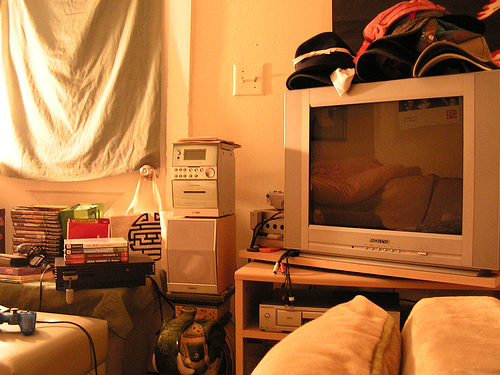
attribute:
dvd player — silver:
[260, 288, 329, 336]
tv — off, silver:
[283, 68, 499, 278]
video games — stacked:
[12, 205, 60, 254]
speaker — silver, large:
[169, 220, 238, 293]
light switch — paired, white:
[235, 64, 265, 94]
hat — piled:
[286, 33, 358, 87]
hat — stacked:
[357, 44, 412, 79]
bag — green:
[61, 202, 104, 223]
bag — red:
[67, 218, 110, 240]